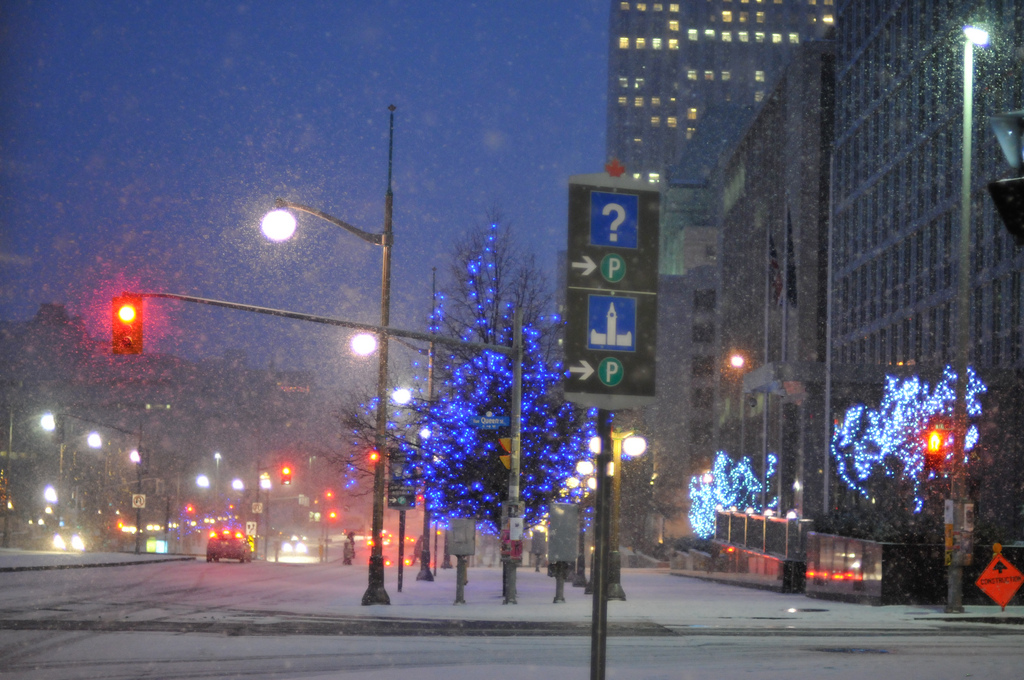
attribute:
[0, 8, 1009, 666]
snowy — weather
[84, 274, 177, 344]
light — traffic light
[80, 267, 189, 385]
light — red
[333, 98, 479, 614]
pole — metal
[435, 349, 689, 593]
lights — blue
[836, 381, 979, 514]
tree — lighted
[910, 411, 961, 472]
light — orange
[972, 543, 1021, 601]
sign — orange, diamond-shaped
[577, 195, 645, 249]
sign — blue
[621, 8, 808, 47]
windows — lighted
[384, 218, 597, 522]
christmas lights — blue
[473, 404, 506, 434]
sign — blue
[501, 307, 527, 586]
pole — white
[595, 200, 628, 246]
question mark — white